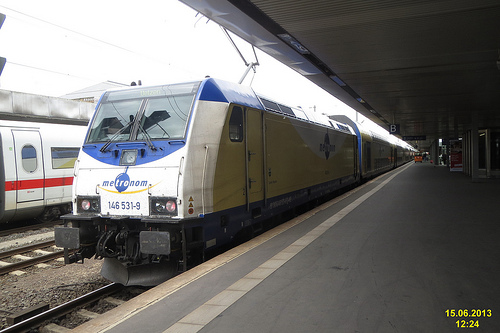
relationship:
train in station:
[71, 95, 360, 217] [397, 195, 431, 220]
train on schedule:
[71, 95, 360, 217] [177, 87, 194, 93]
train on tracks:
[71, 95, 360, 217] [38, 278, 114, 306]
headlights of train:
[149, 195, 179, 219] [71, 95, 360, 217]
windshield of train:
[96, 99, 207, 147] [71, 95, 360, 217]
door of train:
[258, 136, 279, 204] [71, 95, 360, 217]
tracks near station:
[38, 278, 114, 306] [397, 195, 431, 220]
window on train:
[317, 131, 346, 153] [71, 95, 360, 217]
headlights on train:
[149, 195, 179, 219] [71, 95, 360, 217]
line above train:
[299, 222, 336, 240] [71, 95, 360, 217]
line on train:
[299, 222, 336, 240] [71, 95, 360, 217]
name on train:
[309, 143, 337, 160] [71, 95, 360, 217]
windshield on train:
[96, 99, 207, 147] [71, 95, 360, 217]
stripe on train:
[28, 180, 76, 191] [71, 95, 360, 217]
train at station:
[71, 95, 360, 217] [397, 195, 431, 220]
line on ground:
[299, 222, 336, 240] [395, 222, 443, 249]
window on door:
[317, 131, 346, 153] [258, 136, 279, 204]